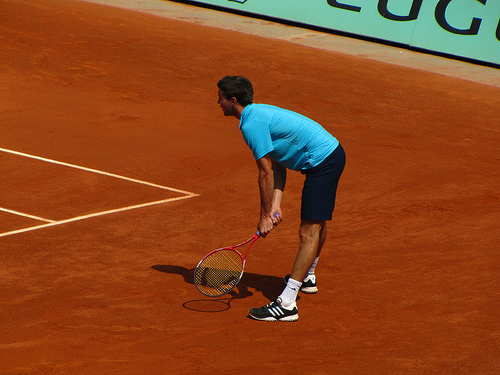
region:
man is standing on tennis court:
[191, 72, 348, 324]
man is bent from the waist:
[201, 75, 347, 229]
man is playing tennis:
[191, 73, 348, 322]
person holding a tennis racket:
[191, 205, 283, 300]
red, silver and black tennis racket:
[190, 210, 280, 299]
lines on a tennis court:
[0, 142, 202, 239]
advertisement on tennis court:
[181, 1, 498, 69]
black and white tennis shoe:
[245, 295, 303, 320]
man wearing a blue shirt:
[213, 73, 341, 170]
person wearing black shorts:
[298, 142, 349, 223]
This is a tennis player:
[133, 91, 472, 344]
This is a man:
[154, 104, 385, 326]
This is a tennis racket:
[179, 209, 317, 369]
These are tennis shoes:
[224, 283, 311, 361]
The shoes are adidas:
[246, 271, 304, 330]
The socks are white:
[248, 246, 326, 307]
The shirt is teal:
[215, 80, 350, 185]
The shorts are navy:
[270, 189, 408, 245]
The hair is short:
[188, 67, 299, 149]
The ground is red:
[41, 200, 146, 364]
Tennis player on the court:
[188, 60, 363, 340]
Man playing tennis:
[167, 53, 369, 336]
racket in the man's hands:
[180, 210, 287, 307]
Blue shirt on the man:
[207, 93, 345, 187]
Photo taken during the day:
[17, 12, 486, 366]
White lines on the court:
[2, 136, 217, 236]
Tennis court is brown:
[12, 14, 494, 365]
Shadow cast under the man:
[133, 243, 306, 303]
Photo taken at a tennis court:
[0, 12, 485, 365]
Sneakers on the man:
[227, 260, 347, 330]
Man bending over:
[214, 73, 347, 324]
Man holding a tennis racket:
[190, 73, 349, 325]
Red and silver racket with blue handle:
[191, 210, 283, 297]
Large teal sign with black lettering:
[192, 0, 499, 65]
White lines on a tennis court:
[0, 147, 199, 252]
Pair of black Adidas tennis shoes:
[247, 272, 317, 326]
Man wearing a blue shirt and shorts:
[214, 73, 348, 325]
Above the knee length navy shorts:
[298, 142, 345, 224]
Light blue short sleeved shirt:
[240, 100, 339, 172]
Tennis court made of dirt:
[1, 0, 498, 374]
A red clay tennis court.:
[0, 26, 262, 346]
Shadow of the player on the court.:
[128, 240, 324, 322]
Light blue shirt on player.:
[210, 87, 345, 207]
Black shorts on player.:
[288, 137, 359, 250]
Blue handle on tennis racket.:
[230, 205, 295, 251]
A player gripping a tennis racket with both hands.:
[181, 67, 358, 352]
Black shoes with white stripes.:
[240, 276, 331, 326]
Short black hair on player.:
[198, 68, 275, 131]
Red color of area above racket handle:
[225, 226, 269, 267]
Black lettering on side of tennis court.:
[302, 0, 498, 80]